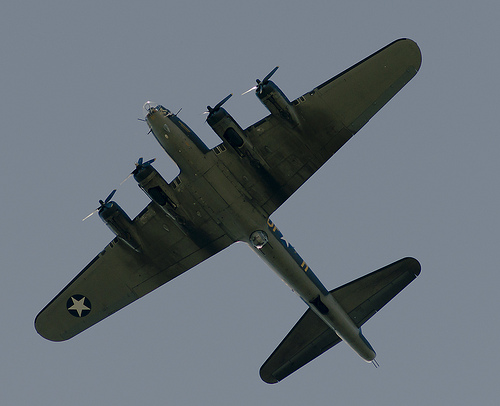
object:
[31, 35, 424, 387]
plane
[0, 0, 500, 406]
air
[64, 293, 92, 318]
logo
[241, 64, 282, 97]
propeller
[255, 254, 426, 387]
tail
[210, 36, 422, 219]
wing